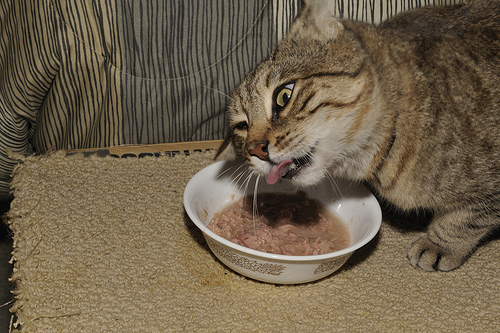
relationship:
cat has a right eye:
[216, 0, 500, 270] [232, 118, 249, 133]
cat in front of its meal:
[216, 0, 500, 270] [182, 157, 383, 286]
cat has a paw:
[216, 0, 500, 270] [406, 233, 466, 271]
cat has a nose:
[216, 0, 500, 270] [247, 141, 271, 161]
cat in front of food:
[216, 0, 500, 270] [200, 185, 351, 258]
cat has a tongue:
[216, 0, 500, 270] [266, 159, 294, 183]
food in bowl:
[200, 185, 351, 258] [183, 157, 383, 284]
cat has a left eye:
[216, 0, 500, 270] [271, 80, 299, 119]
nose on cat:
[247, 141, 271, 161] [216, 0, 500, 270]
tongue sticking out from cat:
[266, 159, 294, 183] [216, 0, 500, 270]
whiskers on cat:
[216, 141, 379, 243] [216, 0, 500, 270]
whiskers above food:
[216, 141, 379, 243] [200, 185, 351, 258]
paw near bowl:
[406, 233, 466, 271] [183, 157, 383, 284]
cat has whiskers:
[216, 0, 500, 270] [216, 141, 379, 243]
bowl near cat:
[183, 157, 383, 284] [216, 0, 500, 270]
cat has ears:
[216, 0, 500, 270] [214, 0, 345, 160]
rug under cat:
[1, 145, 500, 332] [216, 0, 500, 270]